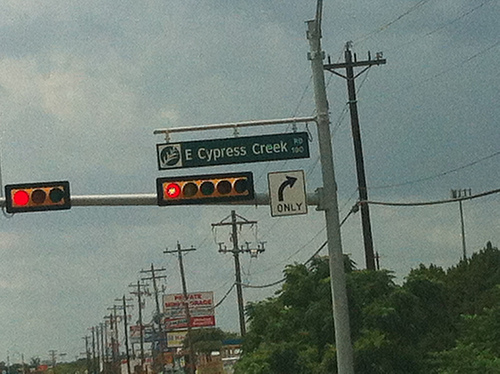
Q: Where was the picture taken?
A: Outside on the street.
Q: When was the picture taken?
A: During the day.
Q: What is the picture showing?
A: Traffic lights and signs.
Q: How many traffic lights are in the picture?
A: Eight.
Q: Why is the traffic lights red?
A: To caution to stop.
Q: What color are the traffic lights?
A: Red.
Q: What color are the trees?
A: Green.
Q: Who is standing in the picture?
A: No one.